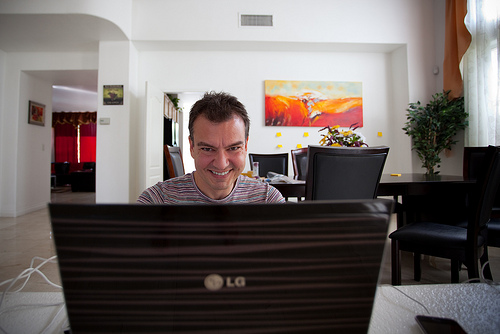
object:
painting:
[265, 80, 362, 128]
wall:
[0, 0, 463, 230]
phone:
[413, 315, 470, 334]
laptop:
[49, 203, 386, 334]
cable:
[377, 282, 432, 313]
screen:
[48, 194, 386, 334]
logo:
[200, 274, 244, 291]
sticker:
[375, 132, 382, 137]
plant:
[403, 87, 470, 180]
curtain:
[441, 0, 500, 147]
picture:
[263, 77, 361, 127]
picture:
[102, 84, 124, 106]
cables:
[0, 247, 63, 301]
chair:
[304, 145, 391, 200]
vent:
[241, 12, 274, 28]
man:
[129, 91, 293, 204]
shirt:
[134, 168, 288, 205]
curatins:
[431, 0, 500, 120]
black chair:
[390, 145, 500, 288]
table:
[0, 0, 500, 334]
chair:
[161, 145, 184, 179]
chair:
[247, 152, 291, 177]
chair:
[290, 146, 309, 179]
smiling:
[204, 167, 237, 178]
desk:
[0, 282, 499, 334]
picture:
[28, 101, 47, 127]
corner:
[331, 37, 444, 164]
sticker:
[275, 132, 282, 137]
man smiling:
[206, 164, 234, 182]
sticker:
[278, 144, 283, 148]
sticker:
[302, 132, 309, 138]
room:
[0, 0, 500, 330]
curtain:
[51, 115, 94, 160]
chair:
[66, 159, 96, 194]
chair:
[52, 159, 71, 189]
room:
[46, 84, 96, 204]